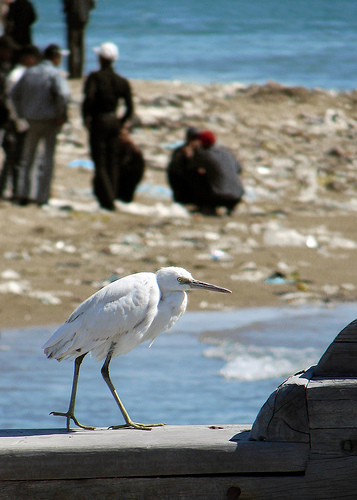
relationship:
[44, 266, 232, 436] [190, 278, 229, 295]
bird has a beak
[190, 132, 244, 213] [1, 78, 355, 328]
person on beach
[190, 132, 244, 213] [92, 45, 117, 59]
person has a cap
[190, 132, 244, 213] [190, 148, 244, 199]
person has a jacket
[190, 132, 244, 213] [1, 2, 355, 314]
person in background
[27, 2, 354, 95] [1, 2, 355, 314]
water in background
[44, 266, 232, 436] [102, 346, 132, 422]
bird has a leg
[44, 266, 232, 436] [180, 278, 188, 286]
bird has an eye